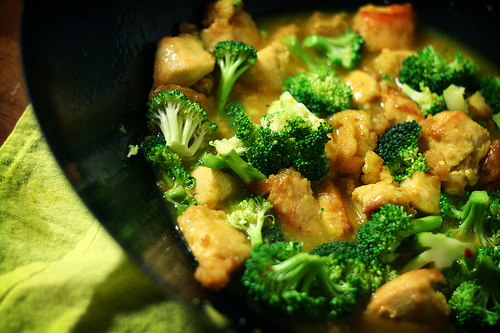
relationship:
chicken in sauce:
[258, 167, 369, 239] [151, 12, 485, 321]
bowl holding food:
[17, 2, 498, 329] [144, 4, 499, 322]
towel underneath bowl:
[7, 108, 145, 329] [17, 2, 498, 329]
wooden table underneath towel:
[1, 0, 28, 151] [0, 101, 193, 332]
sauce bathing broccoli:
[214, 89, 281, 125] [396, 45, 486, 110]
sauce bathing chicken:
[214, 89, 281, 125] [356, 1, 421, 67]